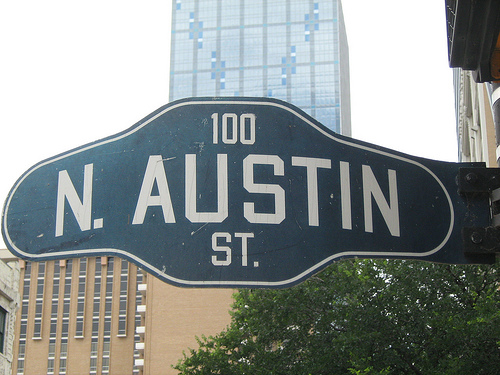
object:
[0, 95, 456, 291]
sign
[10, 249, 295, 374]
building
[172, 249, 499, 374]
tree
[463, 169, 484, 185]
bolt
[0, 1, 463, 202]
sky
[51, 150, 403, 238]
letter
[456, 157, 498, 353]
post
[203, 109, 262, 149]
number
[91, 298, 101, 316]
window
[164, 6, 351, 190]
skyscraper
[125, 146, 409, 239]
text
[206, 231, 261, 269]
abbreviation